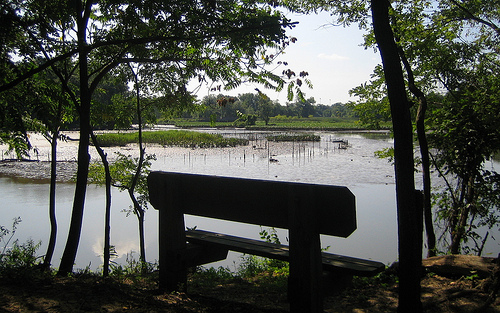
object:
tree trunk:
[361, 7, 448, 297]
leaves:
[247, 35, 248, 38]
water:
[3, 127, 498, 272]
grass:
[162, 110, 452, 131]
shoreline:
[147, 107, 487, 127]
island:
[94, 128, 253, 151]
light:
[420, 249, 489, 311]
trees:
[363, 0, 426, 281]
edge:
[353, 259, 387, 278]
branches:
[86, 59, 121, 92]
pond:
[0, 87, 499, 270]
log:
[328, 134, 353, 146]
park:
[0, 0, 499, 312]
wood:
[146, 170, 353, 238]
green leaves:
[493, 102, 496, 106]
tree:
[428, 0, 499, 256]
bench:
[136, 160, 389, 307]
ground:
[5, 256, 496, 308]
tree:
[55, 0, 95, 271]